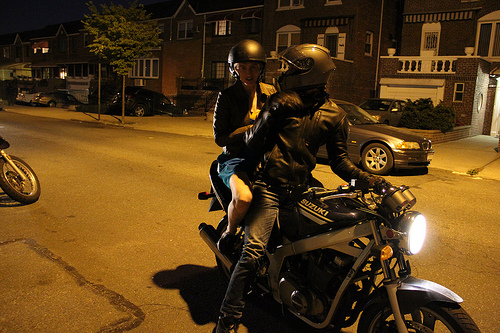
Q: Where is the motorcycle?
A: On the street.